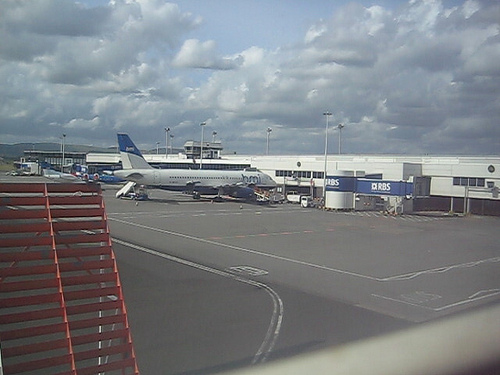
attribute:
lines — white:
[122, 211, 482, 308]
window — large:
[474, 179, 484, 188]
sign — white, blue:
[359, 166, 412, 213]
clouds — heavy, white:
[276, 63, 356, 110]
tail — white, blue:
[117, 131, 153, 169]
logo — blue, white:
[323, 175, 414, 197]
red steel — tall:
[2, 182, 139, 373]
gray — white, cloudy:
[302, 69, 402, 118]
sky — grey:
[233, 10, 281, 37]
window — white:
[312, 171, 318, 178]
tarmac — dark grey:
[5, 172, 498, 361]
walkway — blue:
[2, 167, 491, 373]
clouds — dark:
[104, 40, 394, 130]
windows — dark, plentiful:
[137, 150, 257, 194]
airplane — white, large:
[88, 131, 279, 202]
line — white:
[116, 200, 383, 316]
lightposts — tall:
[196, 119, 207, 162]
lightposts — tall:
[321, 107, 331, 206]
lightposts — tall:
[163, 122, 170, 160]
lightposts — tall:
[58, 132, 65, 176]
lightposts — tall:
[265, 125, 272, 157]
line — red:
[119, 202, 316, 217]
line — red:
[215, 213, 391, 240]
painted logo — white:
[365, 181, 392, 191]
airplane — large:
[111, 130, 275, 200]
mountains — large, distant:
[0, 133, 181, 169]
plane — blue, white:
[111, 131, 276, 201]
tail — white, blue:
[33, 183, 193, 365]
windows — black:
[272, 165, 330, 185]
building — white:
[80, 153, 498, 218]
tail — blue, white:
[79, 131, 149, 187]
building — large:
[86, 147, 494, 215]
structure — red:
[3, 178, 140, 373]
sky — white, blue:
[6, 0, 493, 167]